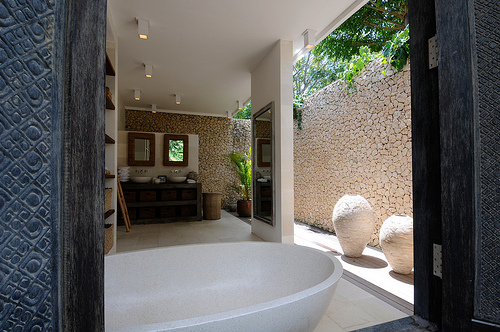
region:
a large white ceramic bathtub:
[113, 242, 350, 327]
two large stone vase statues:
[329, 189, 419, 276]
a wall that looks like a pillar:
[235, 51, 307, 248]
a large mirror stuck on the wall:
[242, 110, 284, 226]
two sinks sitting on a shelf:
[126, 167, 210, 231]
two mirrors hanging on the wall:
[128, 128, 203, 174]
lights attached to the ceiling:
[122, 18, 189, 116]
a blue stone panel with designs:
[22, 89, 77, 299]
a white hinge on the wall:
[428, 227, 455, 287]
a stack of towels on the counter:
[118, 162, 132, 192]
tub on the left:
[133, 249, 305, 314]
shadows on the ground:
[340, 255, 395, 269]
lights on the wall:
[113, 17, 175, 90]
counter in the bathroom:
[122, 175, 224, 216]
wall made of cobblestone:
[316, 133, 383, 190]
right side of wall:
[244, 33, 294, 241]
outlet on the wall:
[420, 235, 455, 280]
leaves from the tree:
[344, 33, 400, 82]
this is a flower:
[161, 134, 185, 162]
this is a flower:
[126, 125, 161, 168]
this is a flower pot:
[212, 136, 260, 222]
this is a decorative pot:
[332, 174, 372, 251]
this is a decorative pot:
[378, 210, 415, 302]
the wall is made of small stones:
[326, 133, 365, 179]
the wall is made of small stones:
[364, 99, 399, 157]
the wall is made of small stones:
[296, 138, 354, 203]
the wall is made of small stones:
[387, 119, 408, 199]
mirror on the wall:
[165, 133, 195, 166]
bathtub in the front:
[146, 260, 311, 322]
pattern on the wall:
[3, 231, 44, 325]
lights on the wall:
[118, 20, 159, 83]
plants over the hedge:
[324, 35, 394, 80]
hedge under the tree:
[318, 147, 379, 179]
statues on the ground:
[320, 191, 381, 266]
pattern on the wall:
[162, 123, 214, 138]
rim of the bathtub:
[284, 292, 335, 304]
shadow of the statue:
[343, 250, 386, 272]